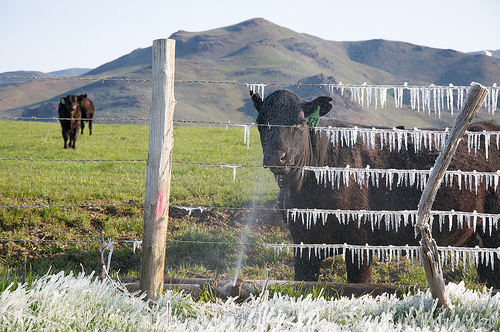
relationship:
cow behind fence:
[247, 90, 500, 291] [0, 37, 499, 329]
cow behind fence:
[243, 87, 495, 272] [113, 36, 495, 307]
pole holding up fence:
[144, 32, 189, 296] [4, 70, 498, 300]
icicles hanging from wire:
[331, 82, 499, 119] [248, 78, 498, 124]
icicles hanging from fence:
[335, 83, 499, 114] [0, 37, 499, 329]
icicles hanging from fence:
[326, 128, 498, 160] [0, 37, 499, 329]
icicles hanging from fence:
[299, 169, 499, 193] [0, 37, 499, 329]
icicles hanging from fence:
[262, 245, 498, 271] [0, 37, 499, 329]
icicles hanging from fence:
[283, 207, 497, 234] [0, 37, 499, 329]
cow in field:
[247, 90, 500, 291] [0, 115, 498, 292]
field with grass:
[3, 120, 290, 329] [11, 272, 127, 329]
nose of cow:
[262, 147, 292, 168] [186, 76, 491, 283]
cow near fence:
[247, 90, 500, 291] [0, 37, 499, 329]